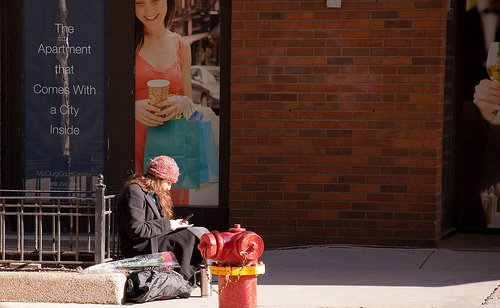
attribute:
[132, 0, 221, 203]
woman — shopping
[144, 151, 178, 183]
cap — red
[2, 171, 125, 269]
fence — metal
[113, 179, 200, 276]
coat — black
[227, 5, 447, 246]
wall — big, brick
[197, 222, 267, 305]
fire hydrant — red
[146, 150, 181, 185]
hat — pink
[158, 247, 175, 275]
roses — red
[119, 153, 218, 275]
woman sitting — writing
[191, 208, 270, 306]
fire hydrant — red, yellow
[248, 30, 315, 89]
brick — multi-colored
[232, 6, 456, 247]
brick wall — red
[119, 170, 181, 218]
brown hair — long